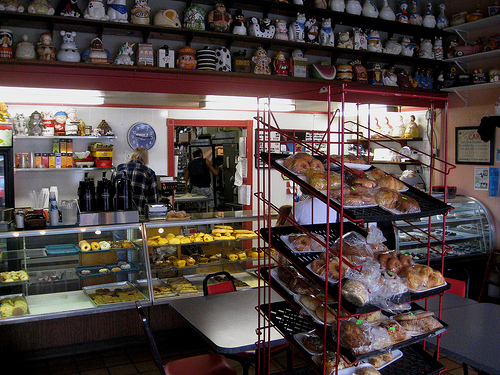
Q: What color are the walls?
A: White.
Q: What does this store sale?
A: Donuts.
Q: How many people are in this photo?
A: Two.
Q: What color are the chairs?
A: Black and red.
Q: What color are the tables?
A: Silver.